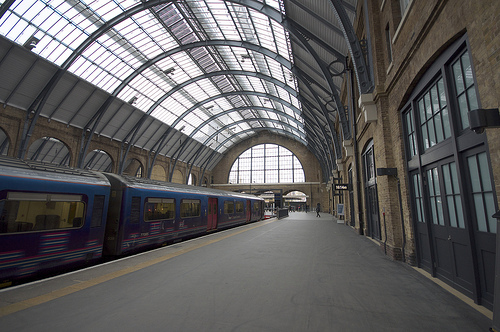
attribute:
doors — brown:
[390, 29, 479, 300]